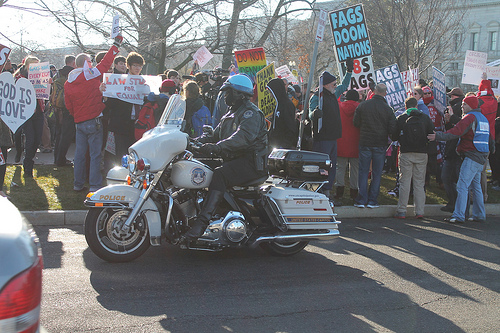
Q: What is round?
A: Tires.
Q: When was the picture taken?
A: Daytime.